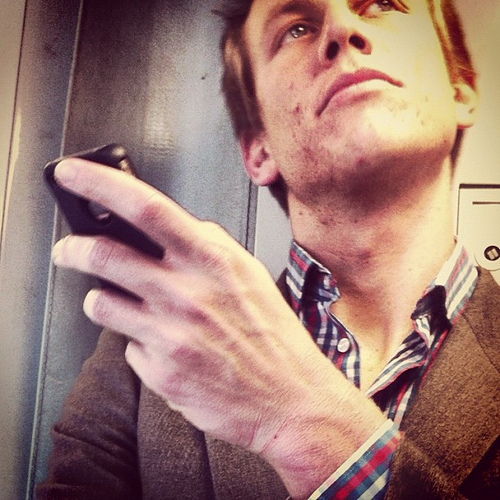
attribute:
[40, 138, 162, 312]
phone — black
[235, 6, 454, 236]
man — young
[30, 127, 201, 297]
cell phone — black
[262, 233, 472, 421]
shirt — red, white, blue, checkered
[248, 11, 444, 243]
man — alone, young, thinking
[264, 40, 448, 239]
man — looking up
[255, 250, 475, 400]
shirt — plaid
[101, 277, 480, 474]
coat — brown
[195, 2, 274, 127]
hair — brown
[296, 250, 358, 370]
buttons — white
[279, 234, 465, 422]
shirt — plaid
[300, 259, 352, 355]
buttons — white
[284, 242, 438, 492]
shirt — plaid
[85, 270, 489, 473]
jacket — blazer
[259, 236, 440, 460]
shirt — plaid